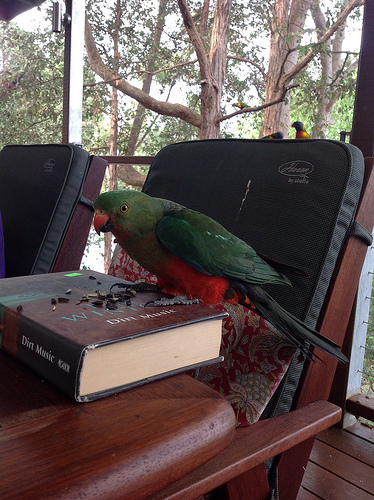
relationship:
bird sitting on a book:
[94, 192, 348, 366] [0, 270, 230, 403]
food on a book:
[16, 275, 135, 313] [0, 270, 230, 403]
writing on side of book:
[21, 334, 75, 372] [0, 270, 230, 403]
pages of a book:
[81, 316, 222, 402] [0, 270, 230, 403]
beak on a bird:
[93, 211, 109, 236] [94, 192, 348, 366]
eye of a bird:
[120, 204, 128, 209] [94, 192, 348, 366]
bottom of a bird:
[157, 255, 250, 305] [94, 192, 348, 366]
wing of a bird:
[155, 208, 291, 286] [94, 192, 348, 366]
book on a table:
[0, 270, 230, 403] [4, 346, 237, 499]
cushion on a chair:
[107, 245, 296, 425] [109, 137, 372, 499]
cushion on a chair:
[2, 142, 91, 279] [1, 143, 108, 279]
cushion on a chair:
[137, 139, 366, 410] [109, 137, 372, 499]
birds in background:
[260, 117, 311, 139] [11, 0, 373, 179]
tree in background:
[84, 0, 301, 139] [4, 4, 371, 144]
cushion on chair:
[2, 142, 91, 279] [3, 139, 107, 268]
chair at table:
[134, 135, 371, 496] [4, 346, 237, 499]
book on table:
[0, 270, 230, 403] [4, 346, 237, 499]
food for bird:
[50, 272, 132, 311] [94, 190, 350, 366]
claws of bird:
[108, 273, 217, 323] [94, 190, 350, 366]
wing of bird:
[155, 215, 293, 289] [94, 190, 350, 366]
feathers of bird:
[232, 278, 349, 366] [94, 190, 350, 366]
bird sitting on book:
[94, 190, 350, 366] [0, 266, 251, 402]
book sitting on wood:
[0, 266, 251, 402] [1, 366, 241, 498]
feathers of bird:
[247, 272, 361, 374] [88, 184, 357, 369]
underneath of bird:
[116, 233, 251, 316] [88, 184, 357, 369]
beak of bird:
[93, 211, 112, 236] [80, 174, 372, 384]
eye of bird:
[120, 204, 128, 213] [88, 184, 357, 369]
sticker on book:
[60, 266, 87, 282] [0, 270, 230, 403]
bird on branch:
[227, 95, 258, 115] [210, 88, 278, 124]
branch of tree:
[210, 88, 278, 124] [106, 47, 273, 215]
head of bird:
[83, 179, 141, 244] [80, 174, 372, 384]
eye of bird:
[120, 204, 128, 213] [80, 174, 372, 384]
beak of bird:
[93, 211, 112, 236] [77, 181, 355, 379]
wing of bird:
[155, 215, 293, 289] [88, 184, 357, 369]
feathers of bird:
[232, 278, 349, 366] [88, 184, 357, 369]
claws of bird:
[110, 281, 161, 292] [80, 174, 372, 384]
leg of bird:
[98, 273, 213, 313] [80, 174, 372, 384]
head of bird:
[93, 190, 141, 237] [88, 184, 357, 369]